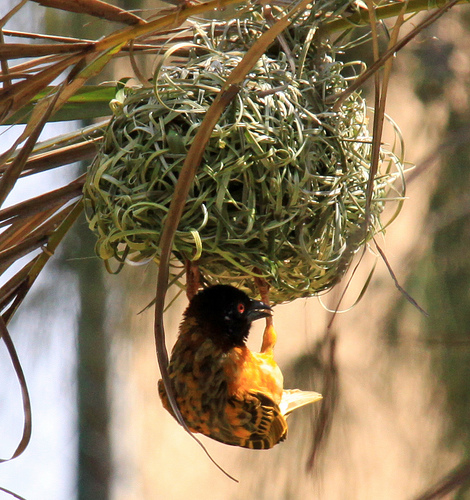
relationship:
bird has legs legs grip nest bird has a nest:
[171, 240, 286, 362] [80, 12, 409, 300]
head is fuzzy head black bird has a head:
[183, 281, 274, 343] [156, 260, 326, 450]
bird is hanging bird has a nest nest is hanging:
[156, 260, 326, 450] [80, 12, 409, 300]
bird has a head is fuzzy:
[158, 278, 323, 450] [178, 281, 274, 350]